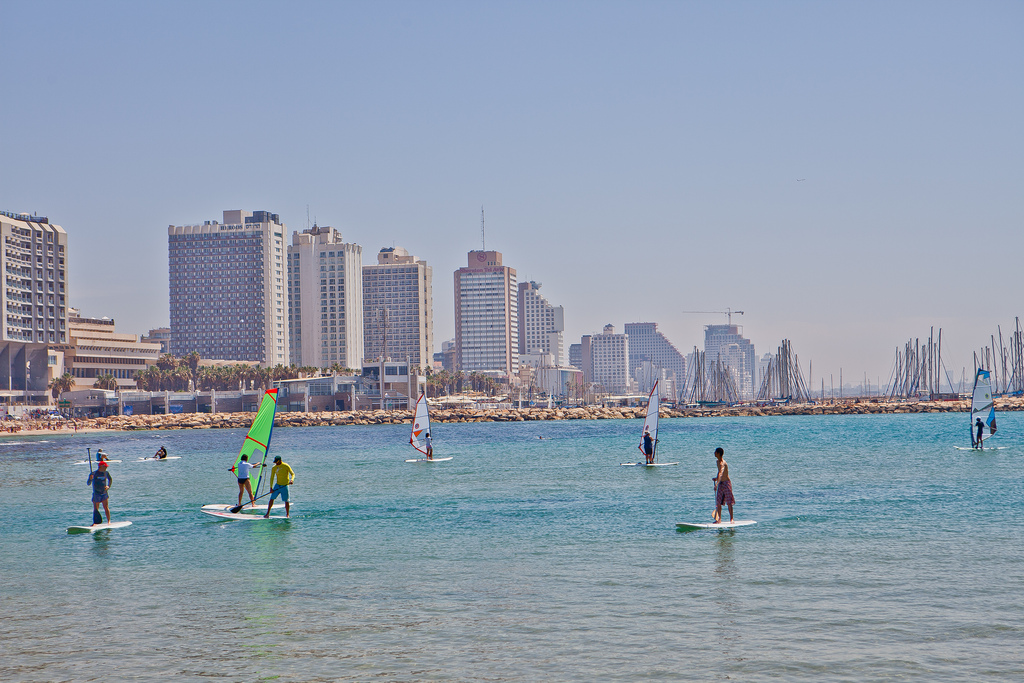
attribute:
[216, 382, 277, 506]
sailboard — green, red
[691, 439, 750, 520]
person — standing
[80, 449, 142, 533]
person — standing